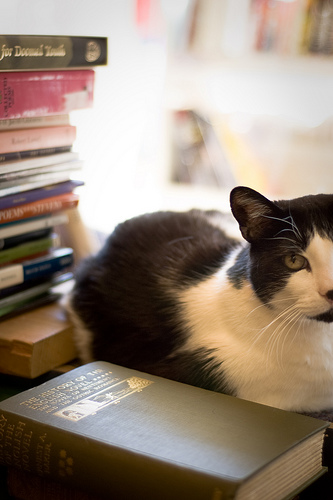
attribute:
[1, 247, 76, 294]
book — blue, white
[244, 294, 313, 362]
whiskers — long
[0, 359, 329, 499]
book cover — light green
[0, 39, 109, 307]
books — stack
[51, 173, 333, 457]
cat — white, black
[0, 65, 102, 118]
book — pink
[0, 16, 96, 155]
book — pink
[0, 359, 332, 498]
book — rectangular, hard covered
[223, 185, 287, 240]
ear — black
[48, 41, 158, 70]
book — thick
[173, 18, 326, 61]
shelf — wooden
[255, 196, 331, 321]
face — white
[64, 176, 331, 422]
cat — white, black, sitting, laying down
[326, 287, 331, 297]
tip — black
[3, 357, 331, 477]
cover — green